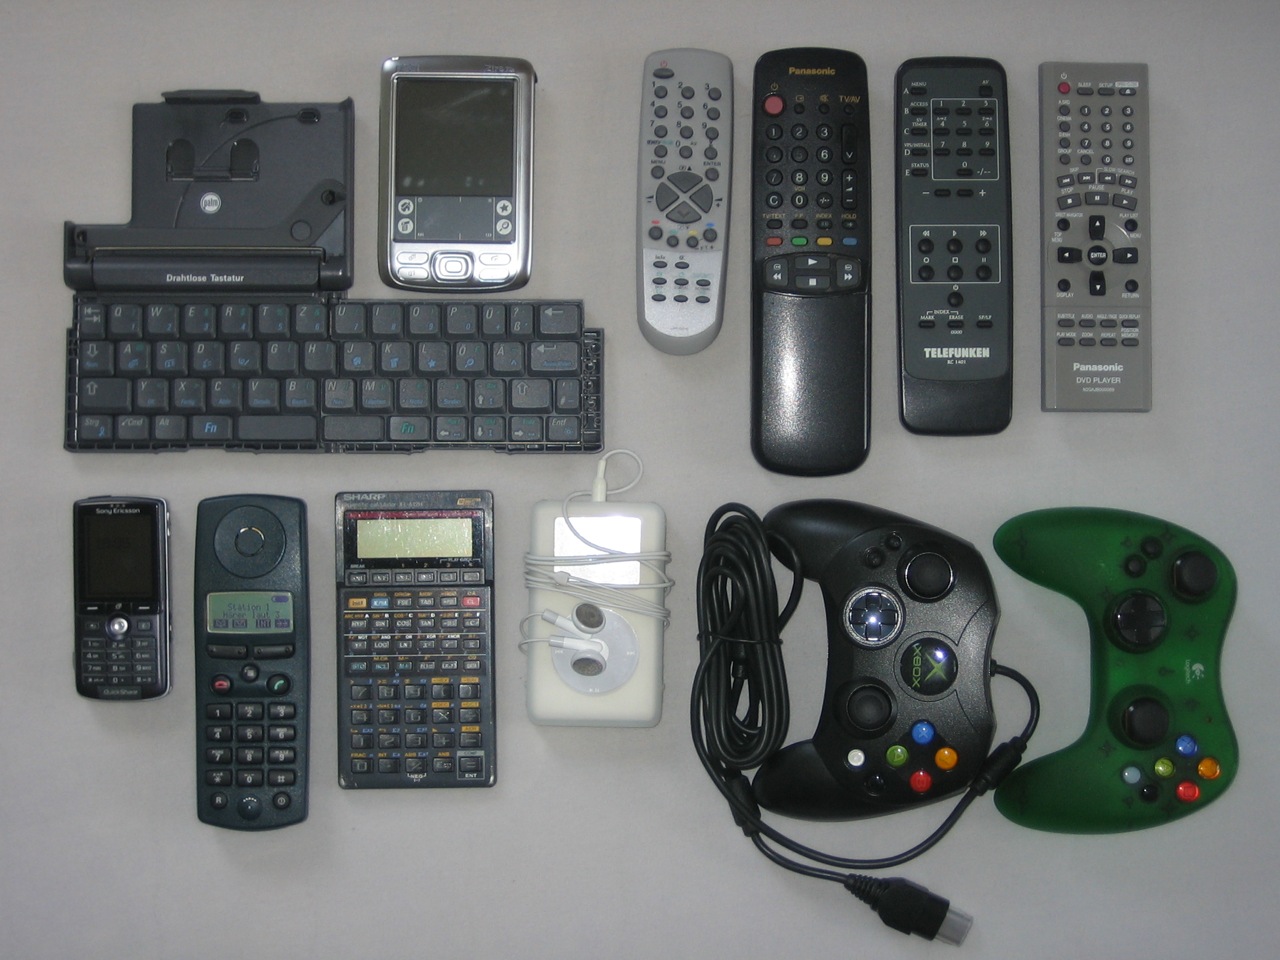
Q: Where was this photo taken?
A: On a table top.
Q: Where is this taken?
A: The table.